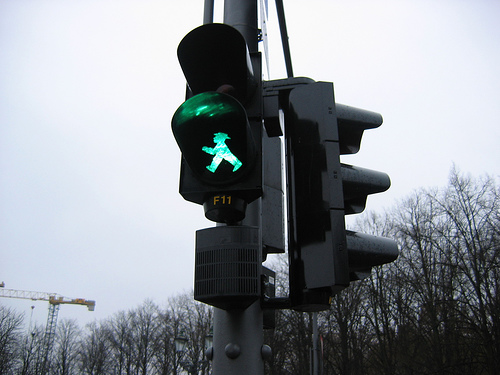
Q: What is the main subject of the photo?
A: A crossing light.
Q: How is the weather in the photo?
A: Cold and overcast.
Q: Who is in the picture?
A: Nobody.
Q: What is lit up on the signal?
A: A little man walking.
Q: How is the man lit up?
A: In green for go.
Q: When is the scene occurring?
A: Late afternoon.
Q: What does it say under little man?
A: F11.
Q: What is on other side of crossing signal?
A: Traffic signal.